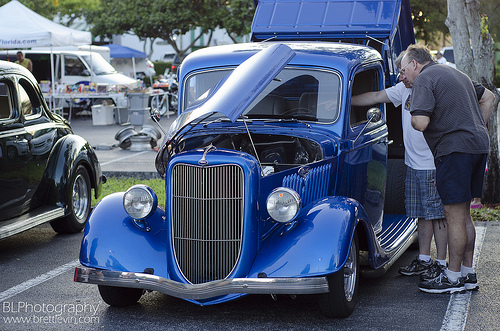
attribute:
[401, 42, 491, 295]
man — looking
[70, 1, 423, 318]
truck — vintage, blue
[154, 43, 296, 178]
hood — up, propped, open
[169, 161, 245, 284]
grill — metal, classic, silver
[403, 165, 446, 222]
shorts — plaid, blue, checkered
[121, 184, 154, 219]
light — round, off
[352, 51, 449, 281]
guy — pointing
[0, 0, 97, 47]
canopy — white, behind, shelter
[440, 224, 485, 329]
line — white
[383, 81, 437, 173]
top — white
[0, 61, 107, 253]
car — black, old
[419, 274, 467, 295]
shoe — gray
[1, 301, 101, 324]
lettering — white, below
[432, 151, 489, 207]
bottoms — blue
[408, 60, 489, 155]
shirt — gray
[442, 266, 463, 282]
socks — white